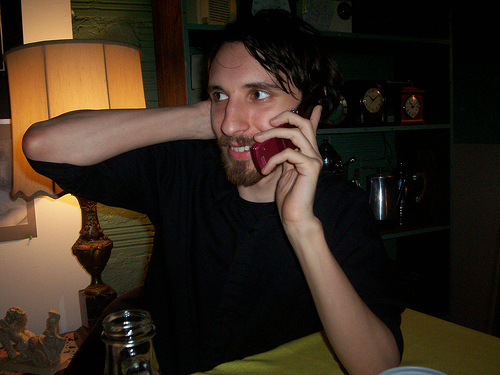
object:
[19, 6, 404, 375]
man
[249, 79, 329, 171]
cellphone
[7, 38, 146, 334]
lamp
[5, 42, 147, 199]
shade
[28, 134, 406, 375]
shirt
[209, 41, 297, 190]
face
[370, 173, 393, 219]
jar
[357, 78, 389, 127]
clock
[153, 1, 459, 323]
shelf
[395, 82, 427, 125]
clock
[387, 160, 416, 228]
pitcher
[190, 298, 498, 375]
table cloth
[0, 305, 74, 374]
statue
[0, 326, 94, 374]
table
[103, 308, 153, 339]
top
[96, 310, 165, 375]
glass bottle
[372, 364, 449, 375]
dish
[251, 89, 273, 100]
eye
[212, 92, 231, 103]
eye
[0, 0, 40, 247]
picture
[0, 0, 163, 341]
wall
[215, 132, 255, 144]
mustache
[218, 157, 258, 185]
goatee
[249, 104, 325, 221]
hand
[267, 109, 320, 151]
finger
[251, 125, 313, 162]
finger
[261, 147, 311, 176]
finger